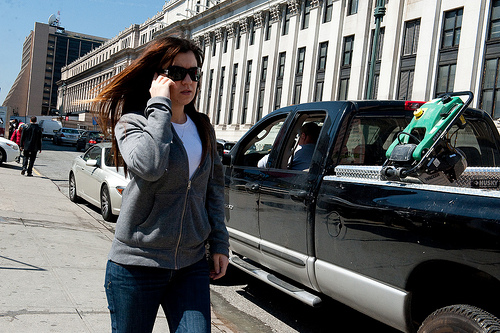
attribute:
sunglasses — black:
[158, 63, 203, 83]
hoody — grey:
[107, 96, 230, 268]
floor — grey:
[0, 160, 228, 332]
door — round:
[326, 211, 343, 238]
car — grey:
[67, 141, 135, 220]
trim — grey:
[225, 225, 407, 333]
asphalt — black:
[23, 138, 88, 191]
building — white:
[54, 0, 500, 142]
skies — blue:
[0, 1, 172, 105]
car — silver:
[51, 126, 84, 146]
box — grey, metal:
[333, 166, 499, 195]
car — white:
[0, 136, 21, 167]